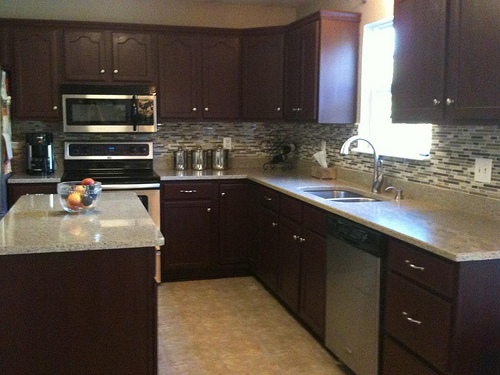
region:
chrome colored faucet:
[338, 131, 387, 194]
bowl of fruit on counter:
[50, 173, 116, 217]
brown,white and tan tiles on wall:
[436, 126, 472, 186]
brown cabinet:
[287, 16, 361, 128]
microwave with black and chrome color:
[63, 90, 165, 139]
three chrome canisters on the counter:
[169, 140, 234, 177]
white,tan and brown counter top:
[31, 216, 161, 246]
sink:
[300, 176, 377, 218]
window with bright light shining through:
[357, 15, 391, 149]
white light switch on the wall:
[471, 154, 496, 186]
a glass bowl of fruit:
[49, 176, 121, 211]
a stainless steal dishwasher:
[313, 197, 399, 374]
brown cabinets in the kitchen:
[162, 169, 485, 373]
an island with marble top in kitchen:
[6, 178, 173, 371]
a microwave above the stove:
[55, 90, 178, 135]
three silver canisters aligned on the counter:
[166, 140, 241, 172]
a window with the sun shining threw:
[347, 10, 454, 185]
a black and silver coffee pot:
[22, 125, 66, 180]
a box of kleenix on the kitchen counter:
[305, 138, 347, 185]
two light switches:
[467, 157, 498, 184]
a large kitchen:
[5, 1, 495, 371]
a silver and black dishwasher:
[315, 205, 390, 370]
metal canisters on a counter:
[160, 132, 231, 185]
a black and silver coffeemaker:
[15, 125, 55, 185]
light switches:
[463, 150, 495, 191]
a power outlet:
[217, 130, 237, 152]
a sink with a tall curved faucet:
[300, 132, 396, 208]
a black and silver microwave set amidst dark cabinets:
[7, 32, 199, 133]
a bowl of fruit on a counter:
[32, 175, 112, 240]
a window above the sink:
[304, 18, 434, 209]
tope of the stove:
[60, 138, 160, 181]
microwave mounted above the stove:
[63, 86, 176, 133]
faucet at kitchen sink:
[344, 131, 399, 198]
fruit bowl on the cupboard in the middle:
[48, 179, 117, 216]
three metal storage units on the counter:
[167, 141, 244, 181]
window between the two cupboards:
[348, 19, 445, 186]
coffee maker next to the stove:
[21, 126, 58, 183]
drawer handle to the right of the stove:
[176, 185, 208, 196]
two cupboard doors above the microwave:
[62, 28, 152, 86]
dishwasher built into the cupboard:
[320, 231, 398, 371]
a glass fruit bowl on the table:
[54, 173, 106, 218]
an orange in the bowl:
[66, 188, 82, 208]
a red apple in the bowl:
[78, 172, 94, 191]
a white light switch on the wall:
[470, 153, 496, 184]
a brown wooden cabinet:
[383, 232, 456, 299]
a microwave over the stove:
[58, 88, 163, 138]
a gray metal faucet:
[332, 125, 388, 196]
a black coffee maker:
[16, 127, 57, 182]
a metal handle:
[398, 249, 433, 277]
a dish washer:
[303, 208, 392, 373]